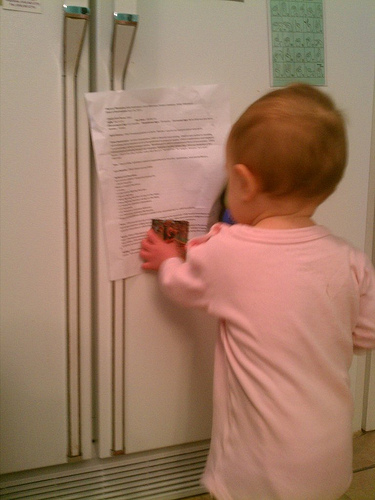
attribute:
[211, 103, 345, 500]
baby — touching, girl, one, holding, standing, playing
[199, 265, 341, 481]
gown — pink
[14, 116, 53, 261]
wall — white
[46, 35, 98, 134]
handles — door, gold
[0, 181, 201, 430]
refrigerator — white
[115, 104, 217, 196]
paper — hung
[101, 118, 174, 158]
writing — black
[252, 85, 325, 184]
hair — blonde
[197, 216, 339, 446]
outfit — pink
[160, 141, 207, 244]
magnet — hanging, holding, green, square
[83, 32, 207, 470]
fridge — white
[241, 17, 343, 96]
poster — green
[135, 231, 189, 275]
hands — tiny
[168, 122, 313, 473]
child — young, small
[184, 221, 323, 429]
shirt — worn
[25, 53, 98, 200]
walls — white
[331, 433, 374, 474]
floor — brown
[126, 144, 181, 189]
letters — black